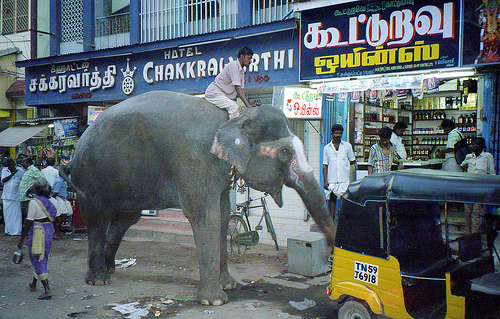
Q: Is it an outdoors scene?
A: Yes, it is outdoors.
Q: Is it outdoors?
A: Yes, it is outdoors.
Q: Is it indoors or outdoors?
A: It is outdoors.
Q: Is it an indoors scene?
A: No, it is outdoors.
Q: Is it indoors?
A: No, it is outdoors.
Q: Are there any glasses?
A: No, there are no glasses.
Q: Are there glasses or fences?
A: No, there are no glasses or fences.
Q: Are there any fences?
A: No, there are no fences.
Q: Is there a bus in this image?
A: No, there are no buses.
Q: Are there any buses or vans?
A: No, there are no buses or vans.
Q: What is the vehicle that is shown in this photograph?
A: The vehicle is a car.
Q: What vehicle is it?
A: The vehicle is a car.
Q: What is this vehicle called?
A: This is a car.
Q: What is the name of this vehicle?
A: This is a car.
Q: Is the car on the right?
A: Yes, the car is on the right of the image.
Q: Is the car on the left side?
A: No, the car is on the right of the image.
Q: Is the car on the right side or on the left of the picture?
A: The car is on the right of the image.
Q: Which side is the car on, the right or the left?
A: The car is on the right of the image.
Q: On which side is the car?
A: The car is on the right of the image.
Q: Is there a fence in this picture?
A: No, there are no fences.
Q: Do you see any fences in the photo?
A: No, there are no fences.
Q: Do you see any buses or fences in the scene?
A: No, there are no fences or buses.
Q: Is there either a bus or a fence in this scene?
A: No, there are no fences or buses.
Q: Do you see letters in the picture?
A: Yes, there are letters.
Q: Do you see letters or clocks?
A: Yes, there are letters.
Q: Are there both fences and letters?
A: No, there are letters but no fences.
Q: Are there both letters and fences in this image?
A: No, there are letters but no fences.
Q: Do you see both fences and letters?
A: No, there are letters but no fences.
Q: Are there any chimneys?
A: No, there are no chimneys.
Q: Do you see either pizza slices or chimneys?
A: No, there are no chimneys or pizza slices.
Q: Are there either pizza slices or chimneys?
A: No, there are no chimneys or pizza slices.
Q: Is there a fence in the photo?
A: No, there are no fences.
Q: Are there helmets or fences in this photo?
A: No, there are no fences or helmets.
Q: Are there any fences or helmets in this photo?
A: No, there are no fences or helmets.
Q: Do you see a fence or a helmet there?
A: No, there are no fences or helmets.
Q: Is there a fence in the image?
A: No, there are no fences.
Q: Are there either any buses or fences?
A: No, there are no fences or buses.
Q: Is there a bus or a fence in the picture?
A: No, there are no fences or buses.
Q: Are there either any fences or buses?
A: No, there are no fences or buses.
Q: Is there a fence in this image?
A: No, there are no fences.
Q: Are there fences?
A: No, there are no fences.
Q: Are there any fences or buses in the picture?
A: No, there are no fences or buses.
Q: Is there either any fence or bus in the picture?
A: No, there are no fences or buses.